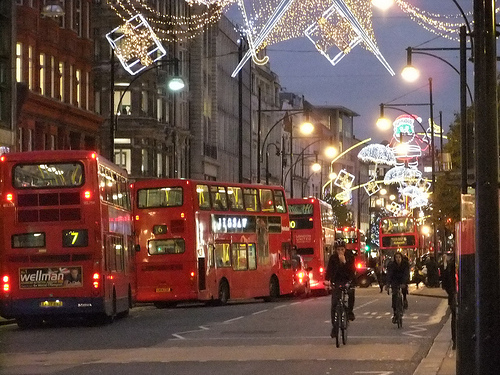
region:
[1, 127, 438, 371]
the buses are red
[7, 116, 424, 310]
the buses have 2 levels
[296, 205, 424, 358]
people are riding bicycles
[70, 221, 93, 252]
number 7 is on bus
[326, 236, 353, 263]
man wearing a helmet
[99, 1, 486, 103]
lights hanging from pole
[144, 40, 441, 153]
street lights are on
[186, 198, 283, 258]
light reflecting off bus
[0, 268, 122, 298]
tail lights are red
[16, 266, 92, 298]
sign says wellman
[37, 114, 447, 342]
many red double decker buses in photo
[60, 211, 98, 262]
yellow number 7 lit up on bus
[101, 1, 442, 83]
christmas lights lit up in photo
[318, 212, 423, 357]
two people riding bikes in photo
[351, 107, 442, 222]
umbrellas lit up above street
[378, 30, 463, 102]
street lamp lit up on street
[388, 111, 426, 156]
green face with santa hat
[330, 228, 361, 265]
person wearing bike helmet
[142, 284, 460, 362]
white lines on road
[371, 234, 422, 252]
yellow writing on back of bus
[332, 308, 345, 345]
tire of the bicycle.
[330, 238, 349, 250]
helmet on man's head.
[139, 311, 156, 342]
shadow on the street.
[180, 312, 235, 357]
white lines on the road.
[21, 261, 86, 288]
sign on front of bus.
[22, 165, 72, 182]
window on the bus.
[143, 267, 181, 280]
red paint on bus.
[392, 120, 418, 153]
christmas lights above street.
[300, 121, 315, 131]
street light on post.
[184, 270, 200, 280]
tail light on bus.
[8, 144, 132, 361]
back of red double decker bus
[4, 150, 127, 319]
lights on double decker bus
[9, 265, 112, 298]
black and white sign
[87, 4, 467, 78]
lit up decorations across roadway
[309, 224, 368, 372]
person riding bicycle on roadway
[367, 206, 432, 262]
red framed sign on building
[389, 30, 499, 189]
street light on black pole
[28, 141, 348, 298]
three red double decker buses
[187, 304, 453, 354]
white painted lines on roadway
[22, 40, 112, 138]
building with lights on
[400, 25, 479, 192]
Light post with light on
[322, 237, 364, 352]
Person riding black bicycle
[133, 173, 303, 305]
Bright red double decker bus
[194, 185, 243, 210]
Passenger windows on bus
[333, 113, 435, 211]
Lighted Christmas decorations hanging from street light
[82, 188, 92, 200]
Red rear light on right side of bus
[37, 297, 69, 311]
Yellow license plate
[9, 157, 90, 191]
Rear view window on upper deck of bus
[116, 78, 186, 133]
Apartment windows on the third floor of building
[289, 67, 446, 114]
Blue sky turning dark